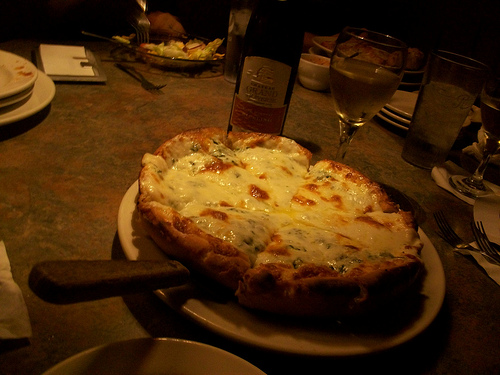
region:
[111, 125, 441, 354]
pizza on white plate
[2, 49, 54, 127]
stack of white plates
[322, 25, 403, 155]
white wine in glass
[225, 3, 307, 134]
wine bottle with label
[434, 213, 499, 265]
prongs of two forks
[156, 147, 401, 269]
melted cheese on pizza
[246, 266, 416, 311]
thicks crust of pizza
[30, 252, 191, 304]
wood handle of server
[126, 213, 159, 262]
shadow of pizza on plate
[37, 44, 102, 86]
white paper clipped to tray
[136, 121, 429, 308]
cheese pizza on a white plate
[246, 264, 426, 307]
brown pizza crust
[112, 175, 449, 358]
white plate under the pizza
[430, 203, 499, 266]
silver forks near the pizza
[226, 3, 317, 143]
bottle of wine with white and red label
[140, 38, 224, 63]
salad on the clear plate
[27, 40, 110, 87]
white check on a silver holder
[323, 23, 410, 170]
clear glass of white wine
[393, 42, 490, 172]
clear cup of ice water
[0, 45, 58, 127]
pile of dirty white plates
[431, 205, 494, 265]
A pair of forks that are touching.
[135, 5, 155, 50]
A fork being used to eat or standing up in food.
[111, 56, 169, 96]
Fork on the table and not touching a napkin.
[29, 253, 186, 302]
The wood handle of a pizza server.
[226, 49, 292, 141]
The label on a dark colored bottle.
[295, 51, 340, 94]
A small white bowl.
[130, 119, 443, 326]
A small sized pizza sitting on a plate.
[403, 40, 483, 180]
A glass of water.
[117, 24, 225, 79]
A mixed salad, being eaten.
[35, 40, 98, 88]
What appears to be a bill for the meal.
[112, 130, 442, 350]
a plate with a pizza on it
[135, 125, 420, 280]
a deep pizza with brown crust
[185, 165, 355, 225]
cheese topping on the pizza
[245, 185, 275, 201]
red sauce on the pizza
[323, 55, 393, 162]
A glass of wine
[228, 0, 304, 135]
a bottle of wine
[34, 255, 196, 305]
the handle of a skillet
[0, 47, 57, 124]
a stack of plates in upper right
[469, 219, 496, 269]
the end of a fork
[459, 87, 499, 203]
the half of a wine glass left of image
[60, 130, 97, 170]
Table where the food, plates, and drinks are on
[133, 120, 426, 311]
Pan of pizza on plate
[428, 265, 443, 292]
Small part of the white plate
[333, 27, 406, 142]
Glass filled with alcohol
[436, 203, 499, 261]
Two silver forks on a napkin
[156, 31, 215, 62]
A bowl of salad someone is eating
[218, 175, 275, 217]
White and brown cheese on pizza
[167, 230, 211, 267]
Brown crust on pizza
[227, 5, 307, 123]
Alcohol bottle on table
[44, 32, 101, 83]
Receipt on the table